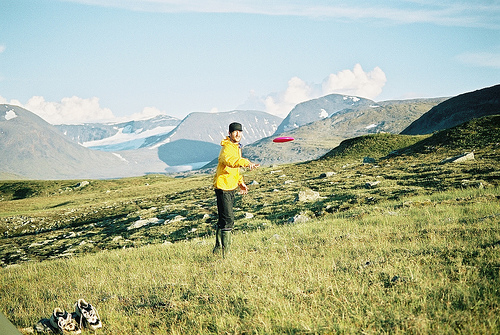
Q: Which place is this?
A: It is a field.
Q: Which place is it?
A: It is a field.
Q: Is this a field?
A: Yes, it is a field.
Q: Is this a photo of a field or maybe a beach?
A: It is showing a field.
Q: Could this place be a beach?
A: No, it is a field.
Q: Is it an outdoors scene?
A: Yes, it is outdoors.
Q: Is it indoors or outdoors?
A: It is outdoors.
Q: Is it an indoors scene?
A: No, it is outdoors.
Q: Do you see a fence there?
A: No, there are no fences.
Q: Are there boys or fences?
A: No, there are no fences or boys.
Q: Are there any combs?
A: No, there are no combs.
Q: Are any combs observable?
A: No, there are no combs.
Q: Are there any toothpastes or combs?
A: No, there are no combs or toothpastes.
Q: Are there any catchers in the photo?
A: No, there are no catchers.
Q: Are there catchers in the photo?
A: No, there are no catchers.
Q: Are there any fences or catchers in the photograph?
A: No, there are no catchers or fences.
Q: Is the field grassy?
A: Yes, the field is grassy.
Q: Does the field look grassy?
A: Yes, the field is grassy.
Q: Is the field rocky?
A: No, the field is grassy.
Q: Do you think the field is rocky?
A: No, the field is grassy.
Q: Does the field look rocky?
A: No, the field is grassy.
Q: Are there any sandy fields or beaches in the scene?
A: No, there is a field but it is grassy.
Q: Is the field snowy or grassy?
A: The field is grassy.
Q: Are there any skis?
A: No, there are no skis.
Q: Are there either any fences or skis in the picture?
A: No, there are no skis or fences.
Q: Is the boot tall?
A: Yes, the boot is tall.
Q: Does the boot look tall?
A: Yes, the boot is tall.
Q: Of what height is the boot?
A: The boot is tall.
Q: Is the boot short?
A: No, the boot is tall.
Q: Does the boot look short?
A: No, the boot is tall.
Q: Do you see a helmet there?
A: No, there are no helmets.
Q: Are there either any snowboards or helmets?
A: No, there are no helmets or snowboards.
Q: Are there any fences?
A: No, there are no fences.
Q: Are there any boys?
A: No, there are no boys.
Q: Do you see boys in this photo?
A: No, there are no boys.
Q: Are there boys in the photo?
A: No, there are no boys.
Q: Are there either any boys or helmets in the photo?
A: No, there are no boys or helmets.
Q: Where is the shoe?
A: The shoe is in the field.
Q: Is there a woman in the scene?
A: No, there are no women.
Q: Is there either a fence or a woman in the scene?
A: No, there are no women or fences.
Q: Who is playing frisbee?
A: The man is playing frisbee.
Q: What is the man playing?
A: The man is playing frisbee.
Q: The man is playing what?
A: The man is playing frisbee.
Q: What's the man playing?
A: The man is playing frisbee.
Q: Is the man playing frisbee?
A: Yes, the man is playing frisbee.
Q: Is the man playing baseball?
A: No, the man is playing frisbee.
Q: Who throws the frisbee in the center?
A: The man throws the frisbee.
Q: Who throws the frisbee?
A: The man throws the frisbee.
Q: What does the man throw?
A: The man throws the frisbee.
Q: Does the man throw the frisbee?
A: Yes, the man throws the frisbee.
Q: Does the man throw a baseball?
A: No, the man throws the frisbee.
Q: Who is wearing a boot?
A: The man is wearing a boot.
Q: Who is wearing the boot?
A: The man is wearing a boot.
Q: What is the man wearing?
A: The man is wearing a boot.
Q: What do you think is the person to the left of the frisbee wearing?
A: The man is wearing a boot.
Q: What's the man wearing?
A: The man is wearing a boot.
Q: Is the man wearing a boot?
A: Yes, the man is wearing a boot.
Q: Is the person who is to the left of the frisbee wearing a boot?
A: Yes, the man is wearing a boot.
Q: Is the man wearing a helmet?
A: No, the man is wearing a boot.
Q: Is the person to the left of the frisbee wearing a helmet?
A: No, the man is wearing a boot.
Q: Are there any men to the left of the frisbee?
A: Yes, there is a man to the left of the frisbee.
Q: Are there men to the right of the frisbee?
A: No, the man is to the left of the frisbee.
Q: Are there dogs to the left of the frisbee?
A: No, there is a man to the left of the frisbee.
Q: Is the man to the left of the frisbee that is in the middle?
A: Yes, the man is to the left of the frisbee.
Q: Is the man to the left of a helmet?
A: No, the man is to the left of the frisbee.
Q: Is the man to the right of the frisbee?
A: No, the man is to the left of the frisbee.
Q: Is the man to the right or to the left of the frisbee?
A: The man is to the left of the frisbee.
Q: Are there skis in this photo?
A: No, there are no skis.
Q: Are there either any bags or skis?
A: No, there are no skis or bags.